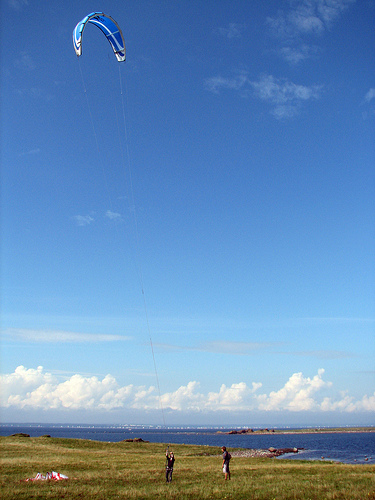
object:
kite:
[25, 469, 65, 482]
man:
[163, 448, 174, 482]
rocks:
[269, 446, 275, 451]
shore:
[202, 446, 304, 451]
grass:
[1, 477, 21, 498]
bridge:
[31, 422, 170, 431]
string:
[121, 76, 130, 167]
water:
[333, 451, 351, 462]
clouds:
[131, 391, 145, 414]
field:
[6, 454, 367, 497]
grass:
[189, 473, 212, 492]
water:
[312, 436, 318, 445]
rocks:
[43, 435, 51, 438]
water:
[289, 436, 325, 445]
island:
[221, 422, 363, 434]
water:
[162, 431, 166, 440]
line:
[144, 292, 155, 360]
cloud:
[274, 75, 298, 115]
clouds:
[26, 360, 41, 409]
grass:
[273, 474, 327, 493]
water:
[348, 432, 370, 438]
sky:
[1, 0, 375, 419]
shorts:
[222, 462, 230, 473]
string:
[161, 409, 168, 434]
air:
[197, 89, 251, 128]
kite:
[70, 12, 128, 64]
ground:
[77, 458, 112, 490]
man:
[218, 447, 231, 482]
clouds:
[322, 370, 341, 414]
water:
[256, 439, 264, 448]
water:
[213, 435, 224, 441]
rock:
[135, 438, 145, 442]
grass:
[3, 441, 20, 455]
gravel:
[262, 452, 264, 454]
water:
[100, 430, 112, 438]